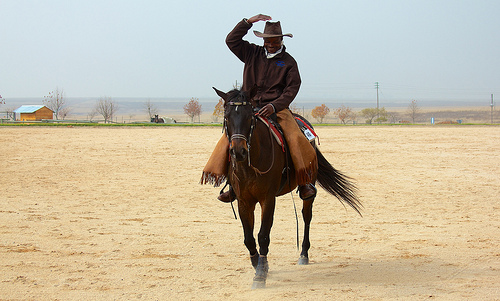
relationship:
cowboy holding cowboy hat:
[196, 12, 322, 208] [252, 19, 295, 39]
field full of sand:
[26, 129, 136, 176] [415, 146, 461, 198]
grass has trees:
[84, 122, 136, 128] [184, 102, 226, 126]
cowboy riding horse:
[196, 12, 322, 208] [212, 84, 279, 207]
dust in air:
[403, 65, 453, 102] [46, 55, 96, 86]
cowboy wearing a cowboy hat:
[196, 12, 322, 208] [258, 25, 284, 38]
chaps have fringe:
[285, 121, 309, 169] [306, 164, 317, 182]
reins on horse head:
[226, 98, 250, 109] [212, 83, 260, 164]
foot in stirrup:
[298, 184, 316, 198] [220, 186, 232, 189]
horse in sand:
[212, 84, 279, 207] [415, 146, 461, 198]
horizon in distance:
[350, 75, 455, 120] [76, 98, 150, 117]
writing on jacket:
[273, 63, 288, 68] [243, 59, 293, 88]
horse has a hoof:
[212, 84, 279, 207] [252, 277, 268, 289]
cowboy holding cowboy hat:
[196, 12, 322, 208] [258, 25, 284, 38]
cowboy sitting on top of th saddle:
[196, 12, 322, 208] [266, 118, 278, 134]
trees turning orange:
[313, 101, 377, 122] [314, 102, 326, 116]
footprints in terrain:
[116, 212, 165, 232] [108, 233, 173, 269]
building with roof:
[10, 100, 62, 124] [14, 106, 46, 114]